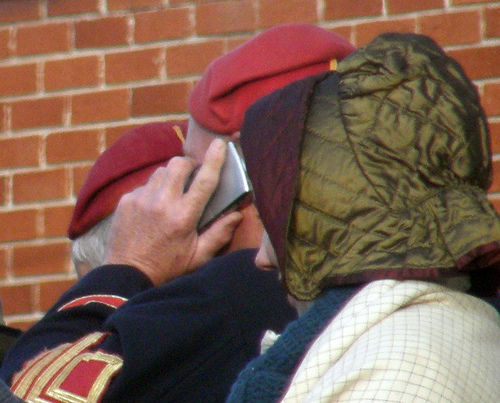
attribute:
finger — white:
[146, 165, 166, 187]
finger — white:
[160, 155, 202, 193]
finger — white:
[188, 134, 228, 222]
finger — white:
[183, 138, 231, 208]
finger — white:
[142, 159, 169, 191]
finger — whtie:
[184, 131, 229, 239]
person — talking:
[0, 20, 362, 401]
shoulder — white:
[308, 290, 499, 397]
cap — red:
[186, 20, 355, 130]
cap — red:
[66, 118, 190, 238]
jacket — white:
[374, 329, 455, 394]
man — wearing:
[144, 40, 378, 319]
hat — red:
[162, 20, 344, 127]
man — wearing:
[1, 114, 297, 401]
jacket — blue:
[1, 262, 295, 401]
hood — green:
[292, 67, 497, 278]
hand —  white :
[153, 182, 202, 222]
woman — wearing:
[229, 32, 489, 397]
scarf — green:
[234, 282, 344, 400]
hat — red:
[185, 23, 359, 134]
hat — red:
[186, 19, 351, 141]